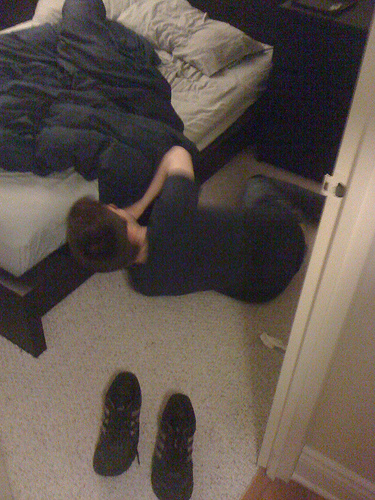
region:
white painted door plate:
[315, 161, 355, 223]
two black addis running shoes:
[79, 366, 205, 497]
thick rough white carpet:
[9, 398, 82, 483]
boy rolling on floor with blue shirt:
[43, 136, 328, 296]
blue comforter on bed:
[8, 11, 190, 166]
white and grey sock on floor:
[249, 328, 299, 366]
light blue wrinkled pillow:
[116, 4, 257, 85]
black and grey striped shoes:
[145, 418, 178, 475]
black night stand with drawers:
[275, 0, 354, 186]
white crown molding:
[276, 428, 338, 498]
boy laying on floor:
[59, 139, 310, 306]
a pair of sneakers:
[90, 366, 207, 498]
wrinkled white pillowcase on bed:
[154, 2, 262, 69]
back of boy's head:
[66, 197, 146, 276]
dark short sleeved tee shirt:
[144, 175, 294, 305]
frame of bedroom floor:
[283, 243, 357, 412]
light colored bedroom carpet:
[9, 393, 84, 447]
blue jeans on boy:
[240, 172, 322, 238]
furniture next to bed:
[259, 5, 348, 137]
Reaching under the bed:
[17, 87, 289, 390]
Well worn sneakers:
[70, 333, 255, 499]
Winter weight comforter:
[1, 0, 215, 145]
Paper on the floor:
[219, 285, 306, 399]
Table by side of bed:
[190, 0, 373, 219]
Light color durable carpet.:
[9, 287, 312, 498]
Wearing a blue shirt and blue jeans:
[54, 129, 341, 344]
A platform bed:
[1, 86, 332, 359]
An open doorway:
[242, 52, 367, 438]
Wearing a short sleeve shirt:
[44, 130, 276, 333]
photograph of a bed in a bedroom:
[5, 6, 372, 498]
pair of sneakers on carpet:
[78, 367, 213, 498]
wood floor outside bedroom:
[247, 470, 323, 498]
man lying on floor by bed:
[64, 143, 324, 302]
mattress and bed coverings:
[0, 6, 266, 169]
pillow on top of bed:
[110, 4, 285, 74]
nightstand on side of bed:
[249, 1, 363, 183]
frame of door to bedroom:
[254, 77, 365, 484]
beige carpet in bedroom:
[64, 303, 249, 373]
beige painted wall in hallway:
[325, 292, 368, 472]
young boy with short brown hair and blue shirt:
[60, 139, 330, 308]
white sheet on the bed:
[162, 39, 248, 114]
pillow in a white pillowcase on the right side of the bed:
[118, 4, 263, 70]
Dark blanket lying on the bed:
[2, 0, 203, 214]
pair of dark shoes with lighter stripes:
[82, 361, 200, 493]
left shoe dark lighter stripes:
[151, 388, 206, 496]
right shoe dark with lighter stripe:
[75, 365, 145, 478]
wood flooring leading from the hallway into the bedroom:
[242, 457, 324, 495]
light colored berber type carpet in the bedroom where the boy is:
[64, 306, 247, 393]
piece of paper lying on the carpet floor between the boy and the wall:
[254, 318, 285, 358]